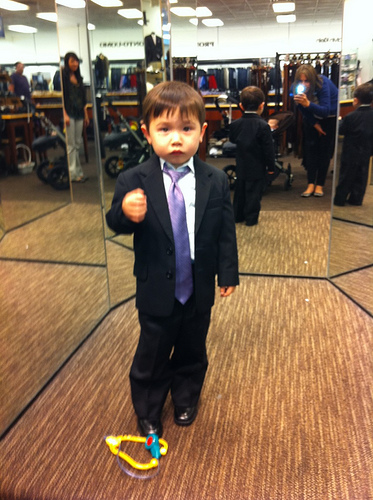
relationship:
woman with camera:
[286, 62, 368, 176] [280, 78, 322, 103]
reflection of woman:
[56, 36, 99, 220] [58, 49, 89, 89]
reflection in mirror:
[56, 36, 99, 220] [57, 49, 93, 57]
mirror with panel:
[0, 1, 372, 442] [2, 1, 111, 456]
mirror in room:
[0, 1, 373, 451] [1, 0, 370, 497]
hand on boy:
[122, 188, 147, 222] [104, 80, 238, 438]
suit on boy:
[103, 151, 241, 424] [105, 78, 238, 437]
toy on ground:
[105, 433, 183, 482] [214, 438, 290, 476]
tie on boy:
[161, 164, 191, 302] [105, 78, 238, 437]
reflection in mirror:
[230, 84, 276, 226] [0, 1, 372, 442]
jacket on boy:
[112, 161, 239, 324] [105, 78, 238, 437]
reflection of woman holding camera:
[286, 62, 337, 199] [293, 79, 309, 101]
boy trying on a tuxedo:
[104, 80, 238, 438] [104, 155, 242, 422]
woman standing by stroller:
[50, 53, 100, 189] [208, 90, 294, 196]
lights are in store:
[262, 0, 308, 31] [0, 0, 371, 497]